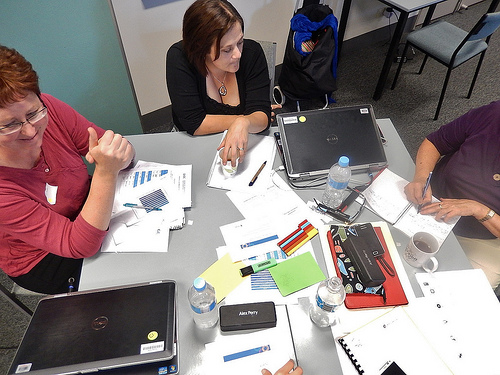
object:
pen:
[248, 160, 268, 186]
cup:
[403, 231, 439, 274]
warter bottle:
[310, 277, 346, 328]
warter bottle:
[188, 277, 218, 329]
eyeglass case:
[219, 301, 277, 332]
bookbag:
[278, 1, 341, 100]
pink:
[11, 182, 39, 230]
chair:
[390, 12, 499, 121]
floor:
[352, 56, 498, 122]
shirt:
[0, 94, 109, 278]